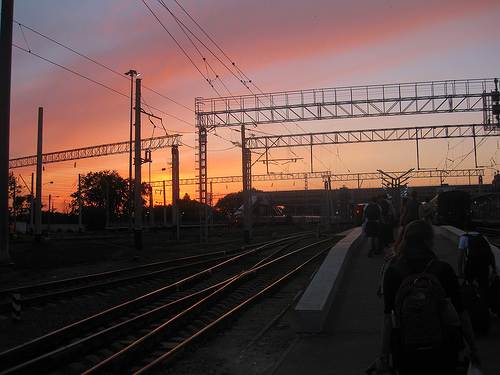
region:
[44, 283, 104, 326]
The rail road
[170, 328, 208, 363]
The rail road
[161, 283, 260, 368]
The rail road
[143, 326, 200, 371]
The rail road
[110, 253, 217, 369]
The rail road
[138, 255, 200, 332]
The rail road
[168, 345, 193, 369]
The rail road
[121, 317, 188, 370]
The rail road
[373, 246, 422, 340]
A backpack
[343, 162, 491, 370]
A backpack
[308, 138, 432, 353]
A backpack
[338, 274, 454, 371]
A backpack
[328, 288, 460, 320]
A backpack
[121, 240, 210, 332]
the rail road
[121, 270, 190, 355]
the rail road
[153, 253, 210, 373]
the rail road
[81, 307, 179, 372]
the rail road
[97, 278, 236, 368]
the rail road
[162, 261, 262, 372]
the rail road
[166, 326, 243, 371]
the rail road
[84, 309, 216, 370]
The rail road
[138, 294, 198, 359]
The rail road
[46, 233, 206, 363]
The rail road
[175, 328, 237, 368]
The rail road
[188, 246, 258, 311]
the tracks are crossing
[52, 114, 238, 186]
the sky is multi-colored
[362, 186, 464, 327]
the people are walking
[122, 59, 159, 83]
the light is on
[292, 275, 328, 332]
the concrete is gray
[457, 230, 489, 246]
the shirt is white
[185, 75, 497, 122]
the structure is metal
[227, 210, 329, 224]
the train is coming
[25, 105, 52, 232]
the pole is thick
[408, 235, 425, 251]
the girl has hair